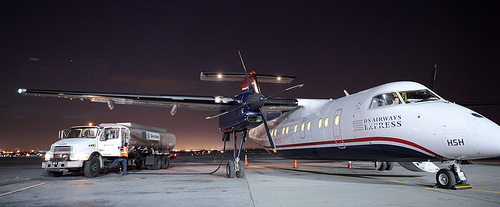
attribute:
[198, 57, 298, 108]
blade — facing down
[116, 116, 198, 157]
tank — silver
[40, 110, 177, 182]
truck — stopped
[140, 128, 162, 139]
sign — white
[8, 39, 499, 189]
airplane — large 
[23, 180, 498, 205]
asphalt — flat 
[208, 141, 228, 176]
fuel line — hanging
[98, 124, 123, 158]
door — open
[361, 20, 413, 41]
sky — dark 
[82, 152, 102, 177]
tire — large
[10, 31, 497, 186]
airplain — small